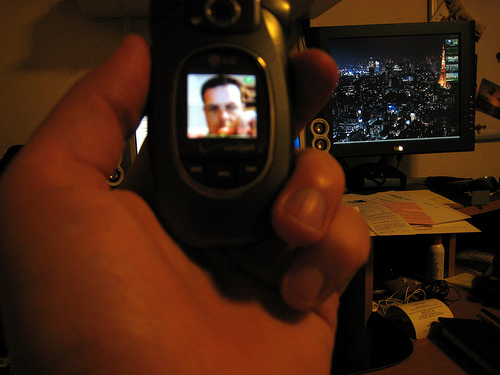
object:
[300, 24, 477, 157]
tv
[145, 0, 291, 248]
cellphone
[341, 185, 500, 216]
board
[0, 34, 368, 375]
person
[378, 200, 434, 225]
paper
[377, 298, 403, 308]
cord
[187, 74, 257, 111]
part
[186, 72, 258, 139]
picture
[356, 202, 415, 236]
receipt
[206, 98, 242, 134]
face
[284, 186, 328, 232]
fingernail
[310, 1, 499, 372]
background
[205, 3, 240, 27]
camera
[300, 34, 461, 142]
picture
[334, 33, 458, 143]
city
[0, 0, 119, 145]
wall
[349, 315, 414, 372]
stuff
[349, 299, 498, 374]
floor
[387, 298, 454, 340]
paper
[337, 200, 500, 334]
table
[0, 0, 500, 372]
room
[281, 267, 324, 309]
fingernails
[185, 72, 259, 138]
cell phone screen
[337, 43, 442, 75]
night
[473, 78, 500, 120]
postcard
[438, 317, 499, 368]
book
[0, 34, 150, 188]
thumb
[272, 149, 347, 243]
finger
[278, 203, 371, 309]
finger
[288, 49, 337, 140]
finger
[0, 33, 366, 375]
hand